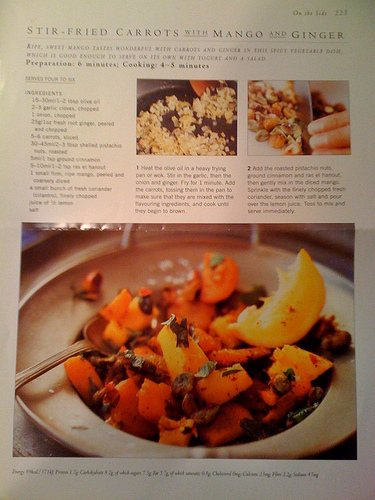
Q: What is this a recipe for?
A: Stir-fried carrots.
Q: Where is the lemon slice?
A: On the plate.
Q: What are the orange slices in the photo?
A: Carrots.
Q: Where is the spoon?
A: In the bowl.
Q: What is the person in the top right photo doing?
A: Chopping food.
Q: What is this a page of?
A: A recipe book.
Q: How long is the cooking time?
A: Four to five minutes.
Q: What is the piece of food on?
A: On a plate.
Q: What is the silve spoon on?
A: On a plate.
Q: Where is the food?
A: On a plate.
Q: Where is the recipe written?
A: On a page.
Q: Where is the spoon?
A: In a bowl.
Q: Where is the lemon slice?
A: On a plate.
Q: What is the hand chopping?
A: Food.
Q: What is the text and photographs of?
A: A recipe.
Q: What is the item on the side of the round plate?
A: A utensil.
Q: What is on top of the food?
A: Lemon wedge.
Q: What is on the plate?
A: Cut ingredients.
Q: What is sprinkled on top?
A: Seasonings.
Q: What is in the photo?
A: Fingers and knife.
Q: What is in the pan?
A: Onions and spoon.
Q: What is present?
A: A newspaper.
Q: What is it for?
A: Reading.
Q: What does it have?
A: Food.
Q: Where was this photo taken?
A: In a cookbook.